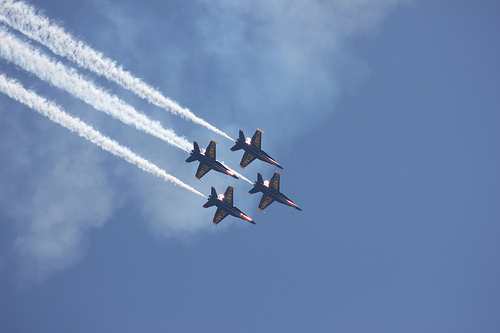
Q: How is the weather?
A: It is clear.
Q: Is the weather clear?
A: Yes, it is clear.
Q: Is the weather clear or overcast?
A: It is clear.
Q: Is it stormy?
A: No, it is clear.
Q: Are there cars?
A: No, there are no cars.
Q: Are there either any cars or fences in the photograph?
A: No, there are no cars or fences.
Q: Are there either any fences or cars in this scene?
A: No, there are no cars or fences.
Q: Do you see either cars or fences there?
A: No, there are no cars or fences.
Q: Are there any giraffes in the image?
A: No, there are no giraffes.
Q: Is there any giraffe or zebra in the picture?
A: No, there are no giraffes or zebras.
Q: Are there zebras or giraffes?
A: No, there are no giraffes or zebras.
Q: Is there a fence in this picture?
A: No, there are no fences.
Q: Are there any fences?
A: No, there are no fences.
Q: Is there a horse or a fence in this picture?
A: No, there are no fences or horses.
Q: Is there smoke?
A: Yes, there is smoke.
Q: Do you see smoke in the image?
A: Yes, there is smoke.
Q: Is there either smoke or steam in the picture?
A: Yes, there is smoke.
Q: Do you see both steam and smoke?
A: No, there is smoke but no steam.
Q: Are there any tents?
A: No, there are no tents.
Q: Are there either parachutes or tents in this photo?
A: No, there are no tents or parachutes.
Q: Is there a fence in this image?
A: No, there are no fences.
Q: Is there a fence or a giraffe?
A: No, there are no fences or giraffes.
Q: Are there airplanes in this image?
A: Yes, there are airplanes.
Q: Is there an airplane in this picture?
A: Yes, there are airplanes.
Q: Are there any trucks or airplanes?
A: Yes, there are airplanes.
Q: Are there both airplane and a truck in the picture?
A: No, there are airplanes but no trucks.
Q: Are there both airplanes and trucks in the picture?
A: No, there are airplanes but no trucks.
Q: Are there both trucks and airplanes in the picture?
A: No, there are airplanes but no trucks.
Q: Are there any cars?
A: No, there are no cars.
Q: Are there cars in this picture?
A: No, there are no cars.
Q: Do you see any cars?
A: No, there are no cars.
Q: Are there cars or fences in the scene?
A: No, there are no cars or fences.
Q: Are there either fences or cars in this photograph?
A: No, there are no cars or fences.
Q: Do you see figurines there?
A: No, there are no figurines.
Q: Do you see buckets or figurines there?
A: No, there are no figurines or buckets.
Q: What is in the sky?
A: The clouds are in the sky.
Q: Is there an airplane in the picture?
A: Yes, there are airplanes.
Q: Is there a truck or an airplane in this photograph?
A: Yes, there are airplanes.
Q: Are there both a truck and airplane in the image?
A: No, there are airplanes but no trucks.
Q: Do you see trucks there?
A: No, there are no trucks.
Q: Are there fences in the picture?
A: No, there are no fences.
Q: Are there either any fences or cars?
A: No, there are no fences or cars.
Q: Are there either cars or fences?
A: No, there are no fences or cars.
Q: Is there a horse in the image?
A: No, there are no horses.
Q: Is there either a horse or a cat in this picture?
A: No, there are no horses or cats.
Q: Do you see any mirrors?
A: No, there are no mirrors.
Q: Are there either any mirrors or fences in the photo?
A: No, there are no mirrors or fences.